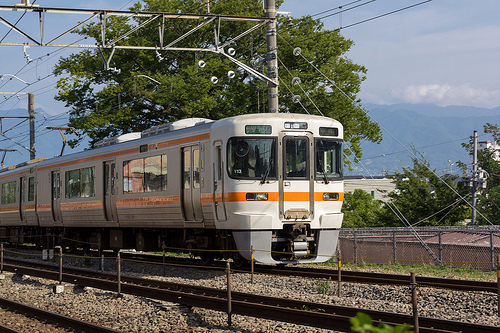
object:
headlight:
[255, 192, 269, 202]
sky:
[0, 0, 499, 119]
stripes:
[0, 133, 212, 180]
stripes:
[0, 191, 343, 215]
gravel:
[0, 248, 499, 332]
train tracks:
[0, 256, 499, 332]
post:
[332, 245, 345, 295]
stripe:
[336, 259, 342, 268]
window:
[140, 154, 161, 193]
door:
[276, 127, 315, 224]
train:
[0, 110, 354, 267]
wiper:
[316, 158, 329, 186]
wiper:
[259, 162, 274, 187]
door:
[190, 144, 204, 222]